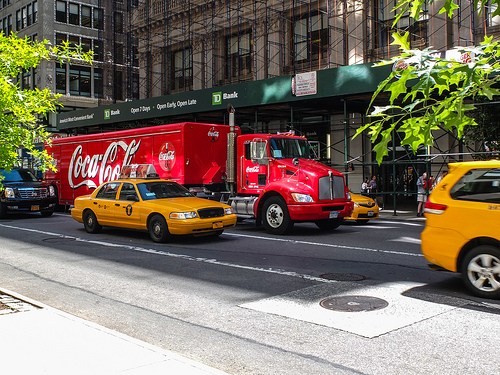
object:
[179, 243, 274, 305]
pizza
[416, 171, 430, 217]
person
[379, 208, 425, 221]
sidewalk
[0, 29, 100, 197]
tree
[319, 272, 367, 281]
manhole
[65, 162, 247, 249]
elephants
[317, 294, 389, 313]
man holes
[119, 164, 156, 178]
advertisement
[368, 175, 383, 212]
person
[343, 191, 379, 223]
taxi cab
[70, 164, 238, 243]
taxi cab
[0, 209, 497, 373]
ground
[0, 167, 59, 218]
black suv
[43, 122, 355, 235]
red truck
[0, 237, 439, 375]
road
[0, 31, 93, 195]
green leaves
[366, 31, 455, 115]
green leaves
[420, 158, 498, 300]
suv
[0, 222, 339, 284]
line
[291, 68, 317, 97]
sign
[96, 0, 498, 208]
building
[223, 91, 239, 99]
bank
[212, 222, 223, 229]
plate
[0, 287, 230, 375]
sidewalk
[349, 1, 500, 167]
tree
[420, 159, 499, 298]
taxi cab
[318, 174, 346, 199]
grill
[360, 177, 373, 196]
pedestrians